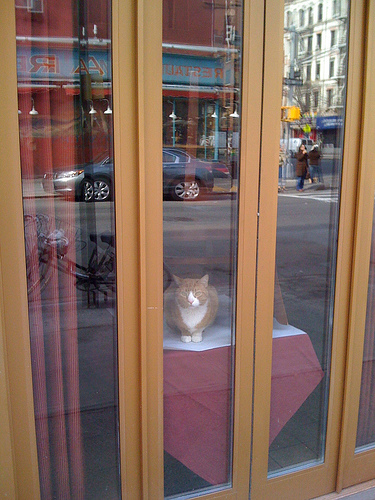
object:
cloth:
[170, 387, 225, 451]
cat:
[159, 268, 220, 344]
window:
[306, 35, 313, 53]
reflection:
[17, 43, 112, 87]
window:
[306, 62, 311, 81]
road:
[22, 153, 341, 304]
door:
[248, 0, 369, 500]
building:
[279, 0, 351, 121]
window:
[317, 0, 324, 23]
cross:
[278, 153, 341, 225]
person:
[294, 142, 309, 192]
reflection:
[23, 214, 171, 313]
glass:
[15, 0, 120, 500]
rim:
[170, 177, 203, 201]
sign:
[281, 106, 301, 123]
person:
[308, 144, 323, 185]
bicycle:
[24, 214, 174, 311]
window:
[330, 29, 337, 49]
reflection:
[282, 74, 306, 88]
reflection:
[281, 103, 305, 123]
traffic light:
[282, 105, 301, 121]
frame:
[0, 0, 42, 500]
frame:
[110, 0, 167, 500]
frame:
[230, 1, 266, 492]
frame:
[323, 0, 374, 484]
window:
[315, 31, 322, 52]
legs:
[180, 329, 192, 343]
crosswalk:
[277, 189, 340, 203]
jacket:
[294, 149, 309, 177]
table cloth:
[163, 335, 324, 487]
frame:
[247, 0, 284, 500]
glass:
[268, 0, 350, 477]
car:
[41, 146, 232, 201]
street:
[23, 153, 341, 308]